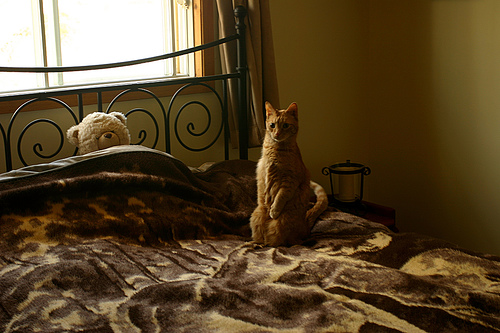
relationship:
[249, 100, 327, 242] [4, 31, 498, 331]
cat on bed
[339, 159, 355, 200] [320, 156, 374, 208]
candle in basin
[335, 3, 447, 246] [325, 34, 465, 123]
shadow on wall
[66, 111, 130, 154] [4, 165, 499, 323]
teddy bear under covers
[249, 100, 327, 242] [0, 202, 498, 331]
cat on bed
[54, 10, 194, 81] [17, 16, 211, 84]
sun in window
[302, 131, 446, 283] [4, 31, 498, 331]
table on right of bed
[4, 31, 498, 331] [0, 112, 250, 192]
bed has bed edge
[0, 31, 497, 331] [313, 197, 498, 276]
bed has bed edge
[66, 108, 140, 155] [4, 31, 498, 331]
teddy bear in bed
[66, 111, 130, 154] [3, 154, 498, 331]
teddy bear under covers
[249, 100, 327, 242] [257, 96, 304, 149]
cat has head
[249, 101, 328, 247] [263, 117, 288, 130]
cat has eyes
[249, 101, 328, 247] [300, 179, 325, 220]
cat has tail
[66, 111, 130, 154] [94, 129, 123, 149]
teddy bear has face